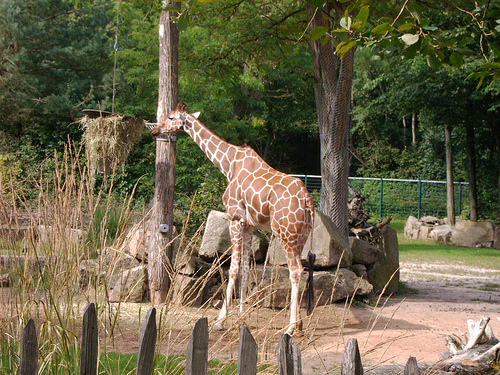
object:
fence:
[296, 174, 483, 235]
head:
[150, 101, 189, 138]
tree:
[452, 0, 500, 218]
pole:
[146, 0, 179, 306]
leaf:
[398, 33, 420, 46]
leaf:
[339, 16, 352, 31]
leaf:
[334, 38, 359, 60]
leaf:
[371, 22, 396, 36]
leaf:
[396, 22, 415, 32]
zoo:
[2, 2, 496, 373]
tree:
[182, 2, 478, 282]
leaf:
[333, 32, 348, 42]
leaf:
[303, 26, 329, 41]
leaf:
[397, 22, 413, 31]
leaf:
[439, 38, 458, 48]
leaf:
[458, 36, 474, 47]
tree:
[293, 0, 366, 244]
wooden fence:
[12, 303, 417, 375]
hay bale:
[76, 112, 145, 182]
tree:
[145, 2, 181, 303]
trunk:
[317, 114, 348, 237]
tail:
[302, 195, 317, 317]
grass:
[3, 106, 411, 373]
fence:
[16, 302, 381, 374]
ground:
[0, 248, 497, 373]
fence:
[375, 169, 421, 217]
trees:
[259, 62, 282, 162]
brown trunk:
[149, 0, 182, 301]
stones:
[348, 236, 383, 263]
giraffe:
[148, 101, 316, 339]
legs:
[209, 202, 247, 332]